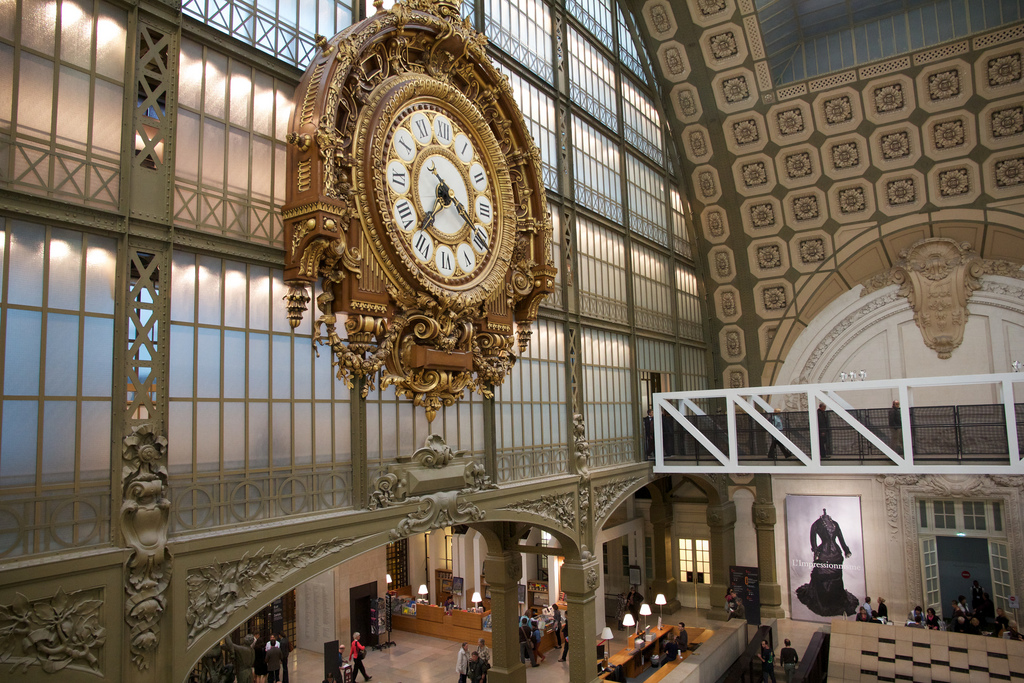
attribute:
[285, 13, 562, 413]
clock — fancy, gold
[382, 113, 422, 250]
circles — white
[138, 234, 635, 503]
panel — clear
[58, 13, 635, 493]
panel — clear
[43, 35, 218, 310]
glass — clear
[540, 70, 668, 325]
glass — clear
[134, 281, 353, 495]
glass — clear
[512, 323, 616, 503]
glass — clear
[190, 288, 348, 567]
glass — clear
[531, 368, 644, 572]
glass — clear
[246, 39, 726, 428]
clock — large , decorative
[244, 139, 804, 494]
clock — golden 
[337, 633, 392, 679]
shirt — red 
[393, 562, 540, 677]
desk — brown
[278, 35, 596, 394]
clock — large , gold , black , white 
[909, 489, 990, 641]
door — white 